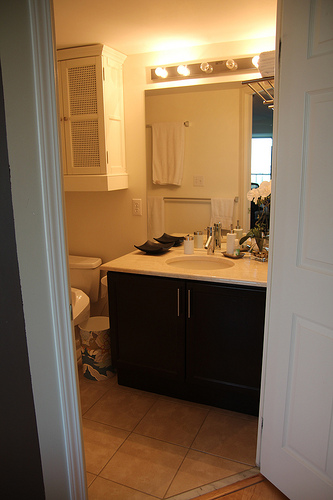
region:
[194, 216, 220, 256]
the faucet is silver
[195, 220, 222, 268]
the faucet is silver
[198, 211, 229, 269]
the faucet is silver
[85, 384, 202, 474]
the floor is tiled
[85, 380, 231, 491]
the floor is tiled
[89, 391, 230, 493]
the floor is tiled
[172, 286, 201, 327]
handles on the cabinet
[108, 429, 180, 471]
the tile on the floor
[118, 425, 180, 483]
the tile is tan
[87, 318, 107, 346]
a trashcan on the floor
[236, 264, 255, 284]
the countertop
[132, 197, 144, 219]
a wall outlet on the wall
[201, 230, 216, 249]
the faucet is silver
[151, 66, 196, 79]
two bright lights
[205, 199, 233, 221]
a towel hanging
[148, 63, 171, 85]
clear light bulb above mirror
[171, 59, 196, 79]
clear light bulb above mirror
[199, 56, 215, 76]
clear light bulb above mirror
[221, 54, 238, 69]
clear light bulb above mirror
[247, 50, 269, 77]
clear light bulb above mirror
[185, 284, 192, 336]
Long metal door handles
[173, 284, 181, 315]
Long metal door handles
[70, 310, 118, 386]
Small floral trash can by cabinet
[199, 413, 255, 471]
Large tile on the floor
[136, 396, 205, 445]
Large tile on the floor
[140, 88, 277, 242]
mirror above the sink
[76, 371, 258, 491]
tiled floor in the bathroom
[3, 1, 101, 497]
white doorframe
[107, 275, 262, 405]
black cabinets under the sink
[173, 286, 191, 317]
silver handles on the cabinets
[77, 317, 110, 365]
trashcan next to the cabinets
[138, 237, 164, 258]
black dish on sink counter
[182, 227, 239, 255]
white dispenser containers on the sink counter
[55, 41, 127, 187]
white cabinet above toilet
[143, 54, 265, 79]
light fixture above mirror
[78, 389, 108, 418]
Small brown groutline on the floor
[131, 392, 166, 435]
Small brown groutline on the floor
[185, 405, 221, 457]
Small brown groutline on the floor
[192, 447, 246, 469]
Small brown groutline on the floor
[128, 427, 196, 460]
Small brown groutline on the floor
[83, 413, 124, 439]
Small brown groutline on the floor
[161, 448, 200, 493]
Small brown groutline on the floor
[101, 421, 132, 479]
Small brown groutline on the floor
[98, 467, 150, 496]
Small brown groutline on the floor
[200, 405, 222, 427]
Small brown groutline on the floor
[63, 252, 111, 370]
a white toilet in a bathroom.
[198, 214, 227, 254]
a sink faucet on a sink.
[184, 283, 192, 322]
A handle on a cabinet